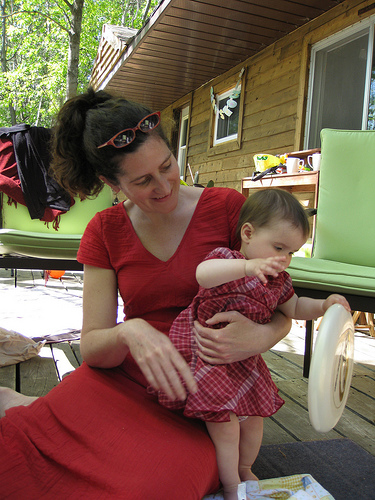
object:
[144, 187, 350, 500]
baby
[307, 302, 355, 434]
frisbee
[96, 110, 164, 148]
red glasses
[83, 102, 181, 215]
woman's head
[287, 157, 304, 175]
mug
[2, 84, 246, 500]
woman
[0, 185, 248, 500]
red dress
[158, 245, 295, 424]
red plaid dress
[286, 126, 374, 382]
chair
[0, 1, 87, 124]
tree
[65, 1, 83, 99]
trunk.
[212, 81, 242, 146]
window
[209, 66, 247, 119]
decorations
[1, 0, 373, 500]
outside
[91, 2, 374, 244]
building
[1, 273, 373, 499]
deck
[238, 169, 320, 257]
table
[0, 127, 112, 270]
back chair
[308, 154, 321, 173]
mug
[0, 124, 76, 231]
baby blanket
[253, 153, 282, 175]
bowl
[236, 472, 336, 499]
blanket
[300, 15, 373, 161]
window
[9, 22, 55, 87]
leaves